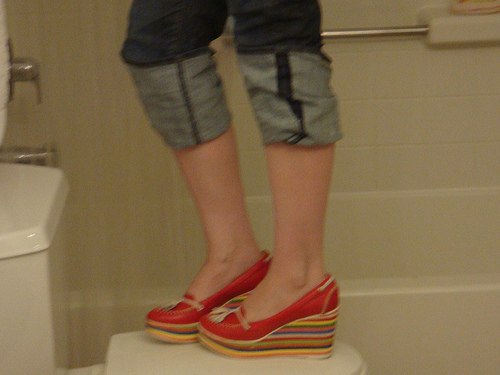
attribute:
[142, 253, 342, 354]
shoes — red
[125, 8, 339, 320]
legs — exposed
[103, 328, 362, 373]
lid — white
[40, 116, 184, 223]
tile — brown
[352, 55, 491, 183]
grey tile — white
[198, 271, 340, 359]
shoe — red, heeled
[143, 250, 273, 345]
shoe — heeled, multi-colored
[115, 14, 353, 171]
jeans — blue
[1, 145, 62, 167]
faucet — silver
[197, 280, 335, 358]
shoe — multi-colored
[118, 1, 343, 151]
jeans — Folded , blue 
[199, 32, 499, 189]
wall — tiled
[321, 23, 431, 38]
metal railing — silver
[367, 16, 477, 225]
wall — tiled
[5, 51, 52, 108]
knob — silver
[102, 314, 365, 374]
toilet seat — lowered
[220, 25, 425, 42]
bar — metal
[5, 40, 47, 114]
handle — shiny, silver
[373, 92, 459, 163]
wall — tiled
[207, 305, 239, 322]
cording — tan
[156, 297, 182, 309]
cording — tan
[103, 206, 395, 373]
shoe — red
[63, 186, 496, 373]
bathtub — white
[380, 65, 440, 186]
wall — tiled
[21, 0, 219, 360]
curtain — clear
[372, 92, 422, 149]
tile — white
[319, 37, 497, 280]
wall — tiled